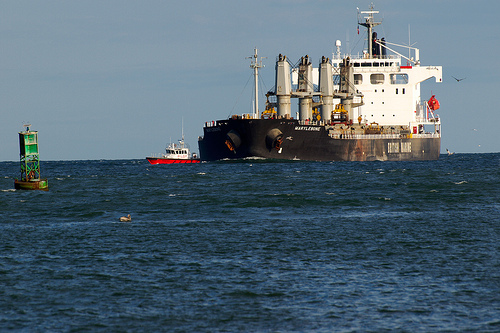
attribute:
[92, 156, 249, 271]
ocean waters — slightly choppy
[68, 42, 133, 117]
sky — grey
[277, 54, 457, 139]
ship — white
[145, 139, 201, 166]
boat — small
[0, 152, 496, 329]
water —  blue, calm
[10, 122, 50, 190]
boat — green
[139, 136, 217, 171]
boat —  White and red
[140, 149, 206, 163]
bottom — red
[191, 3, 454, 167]
bigger boat —  bigger 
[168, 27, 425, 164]
ship —  big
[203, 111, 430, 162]
tanker — black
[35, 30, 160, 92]
clouds — white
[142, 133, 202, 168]
boat —  White and red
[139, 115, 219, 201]
boat —  White and red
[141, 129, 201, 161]
tugboat — white, red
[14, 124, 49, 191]
buoy — green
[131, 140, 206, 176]
boat —  White and red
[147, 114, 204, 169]
smaller boat —  White and red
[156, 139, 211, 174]
boat —  White and red,  bigger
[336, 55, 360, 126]
stacks — grey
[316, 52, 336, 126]
stacks — grey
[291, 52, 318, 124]
stacks — grey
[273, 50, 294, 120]
stacks — grey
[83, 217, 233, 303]
water —  blue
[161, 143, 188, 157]
top — white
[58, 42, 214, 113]
blue sky —  blue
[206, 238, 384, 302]
water —  with ripples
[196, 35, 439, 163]
boat —  bigger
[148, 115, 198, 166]
boat —  White and red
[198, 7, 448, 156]
boat —  bigger 